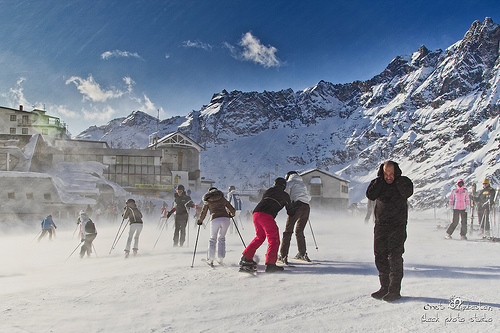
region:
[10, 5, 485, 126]
blue sky with irregular shaped clouds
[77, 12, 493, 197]
rocky mountains mostly covered with snow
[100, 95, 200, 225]
building with glass and triangular overhang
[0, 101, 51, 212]
layers of buildings with square windows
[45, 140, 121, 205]
white panels falling over buildings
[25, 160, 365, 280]
powdery snow blowing around skiers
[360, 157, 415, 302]
man in dark clothing holding his ears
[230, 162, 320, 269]
skater pulling on a skier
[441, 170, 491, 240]
people standing off to the side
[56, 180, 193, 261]
skiers frozen in place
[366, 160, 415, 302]
man is covering his ears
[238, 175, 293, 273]
person wearing red pants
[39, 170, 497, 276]
group of people skiing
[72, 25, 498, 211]
mountains covered in snow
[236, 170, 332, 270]
person holding on to another person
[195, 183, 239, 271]
skiier wearing white pants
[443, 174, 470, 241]
skiier wearing pink and white jacket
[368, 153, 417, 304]
man standing in the snow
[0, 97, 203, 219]
building with lots of windows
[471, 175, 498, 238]
person wearing yellow hat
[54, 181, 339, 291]
people are skiing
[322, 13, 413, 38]
the clear blue sky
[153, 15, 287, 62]
the clouds in the sky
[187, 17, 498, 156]
the steep snow covered mountains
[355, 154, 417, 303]
the person covering both ears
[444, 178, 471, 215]
person with pink jacket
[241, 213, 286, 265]
the person with red snow pants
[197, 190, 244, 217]
the person with brown jacket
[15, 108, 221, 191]
the building behind the people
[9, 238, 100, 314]
wind blowing the snow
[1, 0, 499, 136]
White clouds in the blue sky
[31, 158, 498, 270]
Many people are skiing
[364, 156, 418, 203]
A man is covering his ears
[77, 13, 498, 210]
White snow is on the mountains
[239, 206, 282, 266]
The ski pants are red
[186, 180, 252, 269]
A skiier is holding two ski poles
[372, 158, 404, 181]
A pair of black gloves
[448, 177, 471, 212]
A pink ski jacket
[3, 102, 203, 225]
A large building in the background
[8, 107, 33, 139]
Four windows on a building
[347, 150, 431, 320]
person wearing a pair of black boots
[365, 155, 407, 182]
head of a person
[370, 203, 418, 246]
body of a person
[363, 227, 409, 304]
lower body of a person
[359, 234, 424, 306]
leg of a person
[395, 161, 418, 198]
arm of a person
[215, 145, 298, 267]
person wearing pink pant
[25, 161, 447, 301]
bunch of skaters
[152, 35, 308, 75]
sky with clouds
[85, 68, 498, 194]
a snowy field and mountains